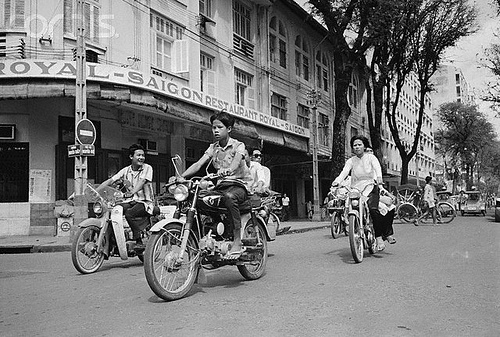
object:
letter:
[9, 59, 30, 75]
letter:
[57, 60, 75, 78]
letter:
[87, 62, 110, 83]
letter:
[124, 68, 148, 86]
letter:
[144, 73, 160, 89]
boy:
[93, 139, 158, 237]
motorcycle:
[66, 175, 183, 279]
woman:
[330, 134, 384, 247]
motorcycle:
[326, 179, 402, 264]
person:
[422, 174, 440, 224]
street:
[1, 216, 496, 335]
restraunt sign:
[1, 53, 318, 149]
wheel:
[140, 221, 203, 301]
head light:
[167, 180, 195, 206]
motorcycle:
[138, 149, 275, 300]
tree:
[376, 4, 449, 190]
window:
[145, 5, 197, 88]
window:
[199, 47, 222, 100]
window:
[233, 63, 257, 108]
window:
[269, 85, 291, 122]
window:
[292, 100, 313, 131]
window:
[314, 106, 336, 146]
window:
[266, 9, 289, 68]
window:
[216, 28, 263, 68]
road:
[427, 259, 470, 294]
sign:
[14, 56, 323, 142]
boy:
[178, 109, 279, 259]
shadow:
[133, 290, 178, 315]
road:
[248, 309, 312, 334]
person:
[342, 143, 402, 215]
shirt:
[337, 150, 374, 202]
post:
[61, 40, 91, 251]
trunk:
[329, 77, 366, 184]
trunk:
[445, 165, 485, 229]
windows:
[429, 81, 440, 113]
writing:
[30, 174, 60, 215]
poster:
[24, 152, 56, 218]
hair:
[189, 92, 270, 127]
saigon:
[97, 63, 202, 110]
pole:
[57, 55, 104, 234]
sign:
[61, 117, 112, 165]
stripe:
[64, 122, 94, 139]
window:
[219, 66, 257, 106]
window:
[265, 13, 299, 94]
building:
[26, 0, 491, 261]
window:
[293, 28, 311, 82]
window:
[313, 43, 332, 93]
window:
[297, 98, 310, 130]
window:
[315, 39, 338, 99]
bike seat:
[232, 186, 261, 206]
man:
[102, 146, 158, 211]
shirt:
[99, 164, 155, 196]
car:
[459, 195, 493, 213]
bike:
[332, 200, 392, 261]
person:
[176, 107, 264, 262]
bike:
[132, 150, 272, 303]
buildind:
[133, 37, 251, 84]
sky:
[345, 1, 497, 143]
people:
[97, 111, 391, 261]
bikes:
[66, 178, 388, 305]